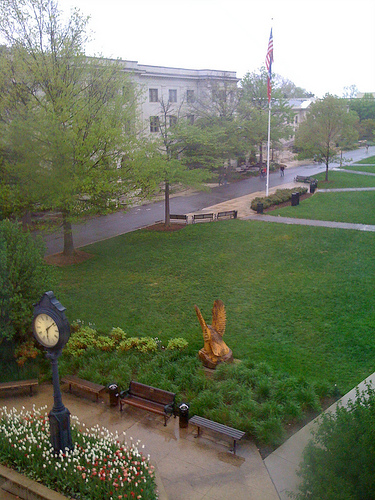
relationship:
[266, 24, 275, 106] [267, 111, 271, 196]
flag on pole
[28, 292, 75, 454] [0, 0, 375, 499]
clock at campus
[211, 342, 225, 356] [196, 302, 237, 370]
golden winged sculpture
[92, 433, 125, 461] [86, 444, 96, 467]
flowers are tiny and white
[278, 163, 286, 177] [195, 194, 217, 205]
people are walking on road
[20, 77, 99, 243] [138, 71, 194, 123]
trees are covering building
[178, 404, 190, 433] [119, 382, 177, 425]
trash cans near bench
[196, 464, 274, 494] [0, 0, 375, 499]
cement walkways thru campus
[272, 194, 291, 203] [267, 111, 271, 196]
bushes near flag pole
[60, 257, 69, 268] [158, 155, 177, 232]
wood chips around tree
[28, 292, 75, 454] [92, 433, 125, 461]
clock tower near flowers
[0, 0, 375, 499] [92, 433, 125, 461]
campus benches with flowers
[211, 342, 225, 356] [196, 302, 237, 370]
golden american eagle statue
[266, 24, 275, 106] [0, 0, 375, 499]
flag of america in campus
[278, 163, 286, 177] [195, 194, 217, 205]
people walking on road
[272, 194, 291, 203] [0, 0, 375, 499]
bushes in campus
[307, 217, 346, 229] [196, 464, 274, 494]
walkway wet cement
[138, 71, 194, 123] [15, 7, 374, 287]
building on college campus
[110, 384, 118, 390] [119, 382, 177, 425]
ashtray next to park bench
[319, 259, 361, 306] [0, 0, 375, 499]
grass green in campus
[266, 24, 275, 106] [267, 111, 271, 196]
flag of america on pole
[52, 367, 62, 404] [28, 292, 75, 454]
black post on clock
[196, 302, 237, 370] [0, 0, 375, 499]
statue carved in campus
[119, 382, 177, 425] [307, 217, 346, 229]
bench near walkway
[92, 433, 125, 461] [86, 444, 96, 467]
flowers are red and white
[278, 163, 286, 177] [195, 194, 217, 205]
people walking down road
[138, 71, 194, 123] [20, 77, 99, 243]
building with many trees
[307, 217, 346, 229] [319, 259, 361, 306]
walkway near grass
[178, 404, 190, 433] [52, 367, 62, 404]
trash can black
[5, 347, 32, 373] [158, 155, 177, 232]
landscaping around tree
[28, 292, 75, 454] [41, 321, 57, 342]
clock with roman numerals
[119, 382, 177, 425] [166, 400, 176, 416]
bench has black arms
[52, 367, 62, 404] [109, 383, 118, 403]
black trash ashtray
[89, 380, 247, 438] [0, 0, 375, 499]
benches in campus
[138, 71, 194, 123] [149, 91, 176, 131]
building with windows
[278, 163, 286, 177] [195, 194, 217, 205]
people walking along road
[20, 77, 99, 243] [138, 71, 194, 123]
trees in front of building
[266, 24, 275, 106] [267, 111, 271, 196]
flag on flag pole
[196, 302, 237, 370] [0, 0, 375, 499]
sculpture in campus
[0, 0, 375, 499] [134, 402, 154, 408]
campus bench brown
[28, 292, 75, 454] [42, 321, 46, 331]
clock black and white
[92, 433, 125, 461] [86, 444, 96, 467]
flowers are pink and white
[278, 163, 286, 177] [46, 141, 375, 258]
people walking on road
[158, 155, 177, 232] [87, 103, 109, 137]
tree light green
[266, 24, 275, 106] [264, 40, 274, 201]
flag on pole